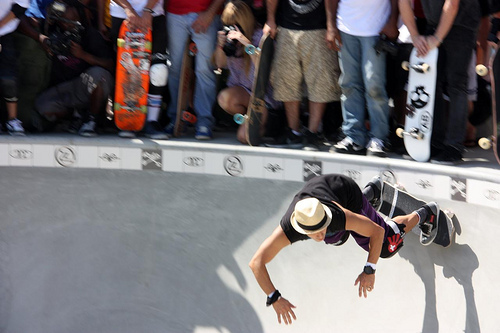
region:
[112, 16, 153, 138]
Blaze orange skateboard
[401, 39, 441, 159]
White skateboard with black decals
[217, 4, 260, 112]
Person holding a camera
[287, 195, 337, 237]
Cream colored hat with black ring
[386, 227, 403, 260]
Red logo on skateboarders shorts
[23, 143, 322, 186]
Design on outer edge of skateboard rink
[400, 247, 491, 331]
Shadow from skateboarder on rink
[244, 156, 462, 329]
Man riding skateboard in rink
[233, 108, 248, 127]
Blue wheel on bottom of skateboard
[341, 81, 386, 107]
Dirt spots on pair of jeans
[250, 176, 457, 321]
man wearing white hat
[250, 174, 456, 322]
man wearing wrist watch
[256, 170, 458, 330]
man wearing black shirt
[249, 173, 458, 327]
man wearing purple shorts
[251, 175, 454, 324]
man wearing black shoes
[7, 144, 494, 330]
man skateboarding in pool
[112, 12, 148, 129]
skateboard design is orange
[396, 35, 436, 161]
skateboard is white with skills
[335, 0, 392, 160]
man wearing blue jeans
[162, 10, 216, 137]
man wearing blue jeans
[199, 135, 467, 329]
the man is skateboarding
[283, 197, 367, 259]
the boy is wearing a fedora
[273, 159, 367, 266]
the fedora has black line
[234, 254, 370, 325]
man is wearing bracelets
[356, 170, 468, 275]
the skateboard is black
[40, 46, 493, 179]
people holding their skateboards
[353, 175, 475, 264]
the sneakers are gray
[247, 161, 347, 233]
the shirt is black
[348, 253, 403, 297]
the watch is black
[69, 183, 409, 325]
the ramp is gray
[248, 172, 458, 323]
a man on a skateboard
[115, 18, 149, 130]
an orange skateboard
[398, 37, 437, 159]
a white and black skateboard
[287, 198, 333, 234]
a man's white fedora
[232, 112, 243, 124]
a blue skateboard wheel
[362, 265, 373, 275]
watch on a man's wrist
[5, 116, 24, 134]
a person's black shoe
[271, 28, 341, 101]
a man's brown and white shorts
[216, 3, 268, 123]
a woman taking a picture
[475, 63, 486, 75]
white skateboard wheel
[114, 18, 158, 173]
Person holding orange skateboard.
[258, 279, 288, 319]
Black band around person's wrist.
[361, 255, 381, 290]
Person wearing black watch.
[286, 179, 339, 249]
Person wearing white hat.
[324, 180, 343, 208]
Person wearing black shirt.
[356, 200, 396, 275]
Person wearing purple pants.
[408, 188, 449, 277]
Person wearing gray and black shoes.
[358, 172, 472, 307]
Person standing on skateboard.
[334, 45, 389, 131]
Person wearing blue jeans.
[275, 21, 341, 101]
Person wearing tan shorts.